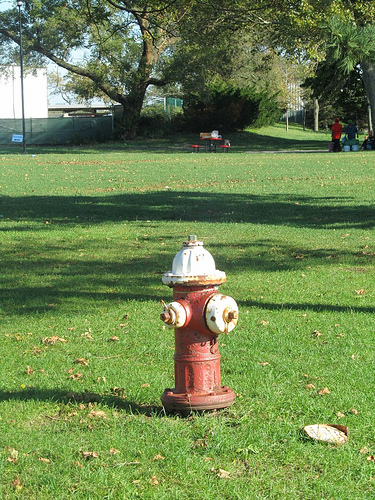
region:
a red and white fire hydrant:
[174, 247, 236, 401]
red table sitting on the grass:
[193, 127, 235, 154]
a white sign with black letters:
[10, 126, 37, 159]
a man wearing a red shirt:
[328, 107, 343, 155]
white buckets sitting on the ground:
[339, 137, 363, 158]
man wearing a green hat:
[345, 116, 364, 149]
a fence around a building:
[30, 106, 126, 160]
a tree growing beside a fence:
[115, 1, 230, 134]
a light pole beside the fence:
[9, 0, 36, 58]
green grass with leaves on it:
[100, 172, 247, 219]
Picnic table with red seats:
[189, 129, 231, 153]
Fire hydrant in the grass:
[148, 226, 246, 417]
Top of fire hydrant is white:
[154, 230, 235, 288]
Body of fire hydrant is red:
[164, 285, 236, 414]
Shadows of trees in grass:
[1, 183, 374, 326]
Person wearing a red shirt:
[325, 113, 345, 152]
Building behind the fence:
[0, 61, 128, 147]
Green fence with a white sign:
[2, 117, 117, 150]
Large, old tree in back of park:
[4, 1, 199, 153]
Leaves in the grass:
[1, 269, 373, 498]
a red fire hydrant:
[159, 233, 240, 411]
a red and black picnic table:
[190, 132, 232, 153]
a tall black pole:
[15, 3, 26, 152]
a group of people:
[332, 117, 374, 152]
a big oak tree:
[0, 1, 273, 138]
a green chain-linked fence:
[0, 115, 110, 145]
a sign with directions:
[11, 133, 22, 143]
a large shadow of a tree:
[0, 192, 374, 330]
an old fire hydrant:
[157, 233, 237, 410]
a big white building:
[0, 63, 47, 133]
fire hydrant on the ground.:
[145, 225, 246, 417]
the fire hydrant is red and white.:
[151, 229, 243, 413]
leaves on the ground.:
[2, 298, 153, 493]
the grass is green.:
[5, 123, 370, 498]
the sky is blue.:
[1, 0, 170, 111]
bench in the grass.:
[185, 123, 234, 156]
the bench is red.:
[186, 128, 234, 153]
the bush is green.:
[179, 71, 285, 137]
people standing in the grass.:
[321, 114, 360, 152]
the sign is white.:
[8, 128, 26, 142]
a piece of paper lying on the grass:
[280, 413, 354, 454]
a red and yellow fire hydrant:
[119, 229, 250, 420]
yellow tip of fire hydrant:
[165, 230, 222, 285]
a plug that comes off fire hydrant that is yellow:
[203, 291, 243, 333]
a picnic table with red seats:
[190, 117, 238, 163]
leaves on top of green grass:
[7, 409, 290, 481]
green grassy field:
[6, 155, 369, 226]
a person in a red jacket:
[329, 115, 344, 155]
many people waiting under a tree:
[324, 111, 374, 153]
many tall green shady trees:
[6, 0, 374, 137]